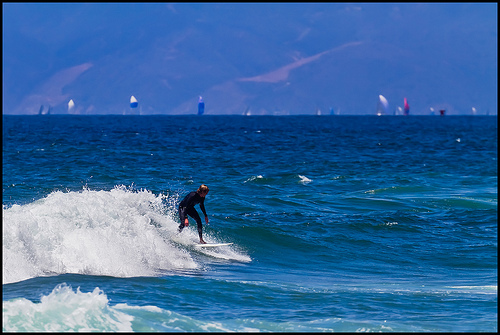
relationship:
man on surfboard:
[176, 180, 212, 245] [192, 242, 238, 247]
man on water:
[176, 184, 209, 245] [6, 118, 499, 332]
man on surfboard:
[176, 184, 209, 245] [192, 242, 233, 247]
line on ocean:
[195, 272, 499, 299] [1, 113, 499, 333]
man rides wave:
[176, 184, 209, 245] [0, 182, 253, 282]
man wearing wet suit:
[176, 184, 209, 245] [172, 188, 209, 243]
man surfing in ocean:
[176, 184, 209, 245] [1, 113, 499, 333]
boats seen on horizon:
[36, 80, 499, 122] [0, 100, 498, 126]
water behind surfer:
[6, 118, 499, 332] [179, 183, 238, 248]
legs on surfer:
[155, 224, 222, 258] [151, 183, 268, 277]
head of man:
[197, 182, 209, 198] [176, 184, 209, 245]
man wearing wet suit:
[176, 184, 209, 245] [175, 193, 207, 239]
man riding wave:
[176, 184, 209, 245] [0, 182, 253, 282]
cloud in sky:
[10, 57, 94, 111] [184, 10, 389, 104]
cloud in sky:
[228, 25, 365, 90] [31, 15, 474, 84]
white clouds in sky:
[244, 17, 364, 95] [3, 0, 498, 115]